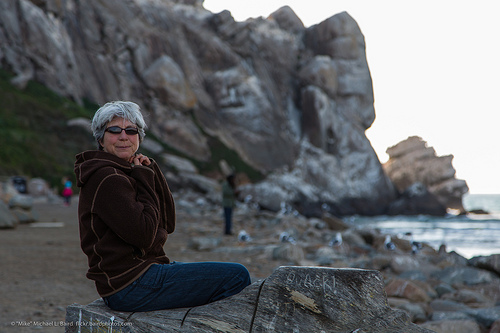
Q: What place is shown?
A: It is a beach.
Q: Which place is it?
A: It is a beach.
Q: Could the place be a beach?
A: Yes, it is a beach.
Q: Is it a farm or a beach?
A: It is a beach.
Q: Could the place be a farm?
A: No, it is a beach.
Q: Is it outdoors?
A: Yes, it is outdoors.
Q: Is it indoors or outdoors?
A: It is outdoors.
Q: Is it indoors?
A: No, it is outdoors.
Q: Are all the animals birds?
A: No, there are both seagulls and birds.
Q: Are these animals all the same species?
A: No, there are both seagulls and birds.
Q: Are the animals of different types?
A: Yes, they are seagulls and birds.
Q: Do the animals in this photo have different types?
A: Yes, they are seagulls and birds.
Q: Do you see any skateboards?
A: No, there are no skateboards.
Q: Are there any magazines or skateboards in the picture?
A: No, there are no skateboards or magazines.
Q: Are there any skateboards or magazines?
A: No, there are no skateboards or magazines.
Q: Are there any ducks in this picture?
A: Yes, there are ducks.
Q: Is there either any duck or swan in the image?
A: Yes, there are ducks.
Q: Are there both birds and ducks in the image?
A: Yes, there are both ducks and a bird.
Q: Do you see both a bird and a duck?
A: Yes, there are both a duck and a bird.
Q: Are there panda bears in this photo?
A: No, there are no panda bears.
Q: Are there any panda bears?
A: No, there are no panda bears.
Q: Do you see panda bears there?
A: No, there are no panda bears.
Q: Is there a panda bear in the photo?
A: No, there are no panda bears.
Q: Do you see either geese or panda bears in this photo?
A: No, there are no panda bears or geese.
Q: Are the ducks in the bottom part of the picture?
A: Yes, the ducks are in the bottom of the image.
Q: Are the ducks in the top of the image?
A: No, the ducks are in the bottom of the image.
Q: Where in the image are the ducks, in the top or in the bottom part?
A: The ducks are in the bottom of the image.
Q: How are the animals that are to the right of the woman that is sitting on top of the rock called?
A: The animals are ducks.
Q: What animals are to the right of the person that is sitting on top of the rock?
A: The animals are ducks.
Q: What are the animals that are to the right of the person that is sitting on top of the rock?
A: The animals are ducks.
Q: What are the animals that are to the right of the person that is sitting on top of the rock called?
A: The animals are ducks.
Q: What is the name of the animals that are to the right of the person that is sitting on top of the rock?
A: The animals are ducks.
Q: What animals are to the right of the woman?
A: The animals are ducks.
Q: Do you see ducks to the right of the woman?
A: Yes, there are ducks to the right of the woman.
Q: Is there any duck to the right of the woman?
A: Yes, there are ducks to the right of the woman.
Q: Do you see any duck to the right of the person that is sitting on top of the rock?
A: Yes, there are ducks to the right of the woman.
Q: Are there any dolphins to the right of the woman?
A: No, there are ducks to the right of the woman.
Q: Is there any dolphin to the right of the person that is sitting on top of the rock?
A: No, there are ducks to the right of the woman.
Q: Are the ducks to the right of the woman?
A: Yes, the ducks are to the right of the woman.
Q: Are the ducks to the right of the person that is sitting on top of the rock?
A: Yes, the ducks are to the right of the woman.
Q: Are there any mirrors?
A: No, there are no mirrors.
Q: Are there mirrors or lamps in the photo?
A: No, there are no mirrors or lamps.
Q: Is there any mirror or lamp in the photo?
A: No, there are no mirrors or lamps.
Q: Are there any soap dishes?
A: No, there are no soap dishes.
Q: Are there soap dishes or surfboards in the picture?
A: No, there are no soap dishes or surfboards.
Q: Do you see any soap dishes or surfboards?
A: No, there are no soap dishes or surfboards.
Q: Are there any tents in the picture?
A: No, there are no tents.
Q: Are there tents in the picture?
A: No, there are no tents.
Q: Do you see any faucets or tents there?
A: No, there are no tents or faucets.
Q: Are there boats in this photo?
A: No, there are no boats.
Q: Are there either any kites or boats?
A: No, there are no boats or kites.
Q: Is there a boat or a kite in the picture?
A: No, there are no boats or kites.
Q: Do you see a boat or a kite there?
A: No, there are no boats or kites.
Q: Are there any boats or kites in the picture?
A: No, there are no boats or kites.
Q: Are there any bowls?
A: No, there are no bowls.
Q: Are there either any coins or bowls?
A: No, there are no bowls or coins.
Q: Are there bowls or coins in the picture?
A: No, there are no bowls or coins.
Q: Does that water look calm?
A: Yes, the water is calm.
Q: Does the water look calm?
A: Yes, the water is calm.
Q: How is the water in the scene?
A: The water is calm.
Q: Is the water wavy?
A: No, the water is calm.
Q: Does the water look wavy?
A: No, the water is calm.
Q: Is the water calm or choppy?
A: The water is calm.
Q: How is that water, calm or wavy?
A: The water is calm.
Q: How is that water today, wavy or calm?
A: The water is calm.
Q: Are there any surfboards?
A: No, there are no surfboards.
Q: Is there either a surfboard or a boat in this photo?
A: No, there are no surfboards or boats.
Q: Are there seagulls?
A: Yes, there is a seagull.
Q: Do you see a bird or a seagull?
A: Yes, there is a seagull.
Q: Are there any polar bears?
A: No, there are no polar bears.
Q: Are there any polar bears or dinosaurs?
A: No, there are no polar bears or dinosaurs.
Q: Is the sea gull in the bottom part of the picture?
A: Yes, the sea gull is in the bottom of the image.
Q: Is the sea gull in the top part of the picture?
A: No, the sea gull is in the bottom of the image.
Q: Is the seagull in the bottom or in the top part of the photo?
A: The seagull is in the bottom of the image.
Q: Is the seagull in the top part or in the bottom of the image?
A: The seagull is in the bottom of the image.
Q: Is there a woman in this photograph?
A: Yes, there is a woman.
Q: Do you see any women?
A: Yes, there is a woman.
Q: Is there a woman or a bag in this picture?
A: Yes, there is a woman.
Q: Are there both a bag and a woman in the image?
A: No, there is a woman but no bags.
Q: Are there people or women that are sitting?
A: Yes, the woman is sitting.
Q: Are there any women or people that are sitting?
A: Yes, the woman is sitting.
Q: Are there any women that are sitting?
A: Yes, there is a woman that is sitting.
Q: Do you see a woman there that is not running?
A: Yes, there is a woman that is sitting .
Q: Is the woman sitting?
A: Yes, the woman is sitting.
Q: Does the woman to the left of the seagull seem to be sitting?
A: Yes, the woman is sitting.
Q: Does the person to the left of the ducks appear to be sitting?
A: Yes, the woman is sitting.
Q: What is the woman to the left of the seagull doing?
A: The woman is sitting.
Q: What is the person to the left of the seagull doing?
A: The woman is sitting.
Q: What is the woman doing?
A: The woman is sitting.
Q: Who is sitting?
A: The woman is sitting.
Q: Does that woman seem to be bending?
A: No, the woman is sitting.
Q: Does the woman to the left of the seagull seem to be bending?
A: No, the woman is sitting.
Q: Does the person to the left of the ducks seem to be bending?
A: No, the woman is sitting.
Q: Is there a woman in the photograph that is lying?
A: No, there is a woman but she is sitting.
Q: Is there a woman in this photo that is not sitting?
A: No, there is a woman but she is sitting.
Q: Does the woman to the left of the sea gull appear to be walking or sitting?
A: The woman is sitting.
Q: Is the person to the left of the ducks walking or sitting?
A: The woman is sitting.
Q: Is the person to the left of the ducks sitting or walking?
A: The woman is sitting.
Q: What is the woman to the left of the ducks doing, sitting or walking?
A: The woman is sitting.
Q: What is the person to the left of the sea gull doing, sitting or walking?
A: The woman is sitting.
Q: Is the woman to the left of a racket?
A: No, the woman is to the left of a seagull.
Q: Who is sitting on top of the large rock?
A: The woman is sitting on top of the rock.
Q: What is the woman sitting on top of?
A: The woman is sitting on top of the rock.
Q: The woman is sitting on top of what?
A: The woman is sitting on top of the rock.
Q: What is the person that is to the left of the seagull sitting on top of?
A: The woman is sitting on top of the rock.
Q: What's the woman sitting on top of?
A: The woman is sitting on top of the rock.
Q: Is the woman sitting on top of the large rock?
A: Yes, the woman is sitting on top of the rock.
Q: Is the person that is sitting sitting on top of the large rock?
A: Yes, the woman is sitting on top of the rock.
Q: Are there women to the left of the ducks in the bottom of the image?
A: Yes, there is a woman to the left of the ducks.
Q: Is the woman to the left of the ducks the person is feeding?
A: Yes, the woman is to the left of the ducks.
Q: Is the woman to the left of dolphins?
A: No, the woman is to the left of the ducks.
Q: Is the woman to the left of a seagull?
A: Yes, the woman is to the left of a seagull.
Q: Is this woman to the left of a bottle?
A: No, the woman is to the left of a seagull.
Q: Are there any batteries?
A: No, there are no batteries.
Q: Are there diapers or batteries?
A: No, there are no batteries or diapers.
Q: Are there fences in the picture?
A: No, there are no fences.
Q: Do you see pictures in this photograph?
A: No, there are no pictures.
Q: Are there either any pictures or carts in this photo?
A: No, there are no pictures or carts.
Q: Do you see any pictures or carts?
A: No, there are no pictures or carts.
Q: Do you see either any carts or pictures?
A: No, there are no pictures or carts.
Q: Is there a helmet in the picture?
A: No, there are no helmets.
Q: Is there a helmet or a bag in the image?
A: No, there are no helmets or bags.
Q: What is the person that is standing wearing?
A: The person is wearing a jacket.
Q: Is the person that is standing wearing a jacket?
A: Yes, the person is wearing a jacket.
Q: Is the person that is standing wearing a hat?
A: No, the person is wearing a jacket.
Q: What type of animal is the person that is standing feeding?
A: The person is feeding the sea gull.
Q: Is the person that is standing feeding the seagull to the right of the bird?
A: Yes, the person is feeding the sea gull.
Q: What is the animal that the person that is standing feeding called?
A: The animal is a seagull.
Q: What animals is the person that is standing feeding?
A: The person is feeding the ducks.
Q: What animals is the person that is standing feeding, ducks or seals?
A: The person is feeding ducks.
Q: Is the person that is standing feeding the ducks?
A: Yes, the person is feeding the ducks.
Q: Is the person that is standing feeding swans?
A: No, the person is feeding the ducks.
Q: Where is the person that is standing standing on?
A: The person is standing on the beach.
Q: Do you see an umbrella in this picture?
A: No, there are no umbrellas.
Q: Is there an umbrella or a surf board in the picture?
A: No, there are no umbrellas or surfboards.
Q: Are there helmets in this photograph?
A: No, there are no helmets.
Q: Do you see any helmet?
A: No, there are no helmets.